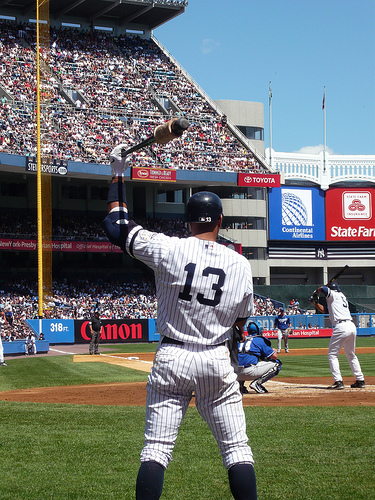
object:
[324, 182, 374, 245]
state farm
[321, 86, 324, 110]
flag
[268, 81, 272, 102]
flag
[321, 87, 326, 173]
pole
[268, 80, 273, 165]
pole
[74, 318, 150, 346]
canon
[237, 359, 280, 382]
pants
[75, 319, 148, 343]
advertising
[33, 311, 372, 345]
wall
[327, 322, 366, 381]
pants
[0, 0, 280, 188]
bleachers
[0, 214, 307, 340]
group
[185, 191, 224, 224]
cap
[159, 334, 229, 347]
belt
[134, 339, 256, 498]
pants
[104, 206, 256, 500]
uniform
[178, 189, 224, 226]
baseball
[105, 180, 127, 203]
black band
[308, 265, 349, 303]
baseball bat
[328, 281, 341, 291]
helmet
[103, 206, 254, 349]
shirt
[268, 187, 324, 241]
ad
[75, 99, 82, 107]
person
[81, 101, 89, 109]
person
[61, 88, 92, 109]
stairway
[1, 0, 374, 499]
stadium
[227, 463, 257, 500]
black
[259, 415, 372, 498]
lawn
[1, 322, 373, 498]
field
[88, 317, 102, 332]
shirt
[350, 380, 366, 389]
shoe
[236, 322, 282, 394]
catcher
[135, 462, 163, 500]
socks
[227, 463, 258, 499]
socks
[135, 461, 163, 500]
black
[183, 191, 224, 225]
black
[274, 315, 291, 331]
shirt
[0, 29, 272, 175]
audience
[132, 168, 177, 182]
banner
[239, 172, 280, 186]
advertisement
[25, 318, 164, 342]
blue wall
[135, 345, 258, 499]
legs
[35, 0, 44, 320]
pole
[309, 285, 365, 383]
uniform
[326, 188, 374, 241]
sign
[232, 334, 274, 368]
shirt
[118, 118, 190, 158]
baseball bat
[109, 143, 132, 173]
hand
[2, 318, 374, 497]
ball field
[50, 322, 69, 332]
318 ft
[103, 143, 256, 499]
batter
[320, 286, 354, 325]
shirt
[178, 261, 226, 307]
13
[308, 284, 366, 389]
man